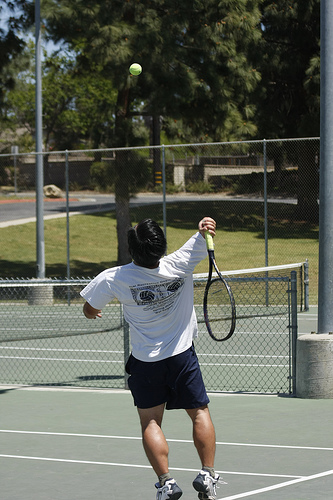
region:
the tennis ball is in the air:
[129, 63, 143, 75]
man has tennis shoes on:
[152, 470, 218, 498]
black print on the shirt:
[127, 276, 184, 314]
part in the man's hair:
[133, 226, 142, 243]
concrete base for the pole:
[295, 332, 332, 398]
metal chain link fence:
[1, 271, 294, 389]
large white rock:
[42, 184, 61, 196]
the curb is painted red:
[0, 198, 76, 203]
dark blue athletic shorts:
[125, 342, 208, 408]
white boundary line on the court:
[220, 464, 330, 498]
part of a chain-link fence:
[195, 272, 300, 396]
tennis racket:
[200, 220, 239, 346]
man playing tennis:
[82, 210, 232, 499]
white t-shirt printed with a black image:
[84, 235, 210, 353]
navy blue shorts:
[121, 342, 214, 413]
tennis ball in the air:
[126, 61, 145, 77]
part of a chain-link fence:
[1, 278, 130, 391]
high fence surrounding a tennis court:
[3, 135, 316, 304]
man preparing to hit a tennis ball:
[82, 211, 235, 497]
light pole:
[24, 58, 59, 305]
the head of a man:
[125, 205, 191, 295]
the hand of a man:
[189, 216, 225, 259]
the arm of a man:
[176, 206, 234, 277]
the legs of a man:
[142, 354, 240, 491]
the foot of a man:
[189, 456, 242, 498]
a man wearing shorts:
[106, 327, 246, 432]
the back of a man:
[126, 190, 199, 284]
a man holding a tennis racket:
[122, 177, 257, 350]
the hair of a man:
[125, 200, 176, 275]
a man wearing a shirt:
[56, 209, 229, 396]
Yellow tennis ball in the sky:
[125, 54, 150, 79]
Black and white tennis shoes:
[155, 461, 226, 499]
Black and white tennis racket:
[196, 212, 244, 369]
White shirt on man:
[67, 231, 232, 384]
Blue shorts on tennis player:
[112, 345, 226, 427]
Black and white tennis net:
[0, 254, 309, 386]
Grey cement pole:
[289, 0, 331, 402]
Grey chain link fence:
[9, 139, 332, 343]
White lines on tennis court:
[9, 290, 322, 499]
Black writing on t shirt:
[125, 273, 194, 316]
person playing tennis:
[84, 236, 246, 490]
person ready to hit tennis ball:
[95, 215, 254, 491]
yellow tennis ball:
[128, 64, 146, 81]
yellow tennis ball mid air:
[121, 48, 146, 77]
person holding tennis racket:
[99, 214, 247, 355]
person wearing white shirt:
[93, 231, 231, 354]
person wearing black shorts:
[123, 333, 208, 409]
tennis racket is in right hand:
[191, 222, 238, 342]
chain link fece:
[11, 287, 68, 320]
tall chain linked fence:
[81, 155, 171, 201]